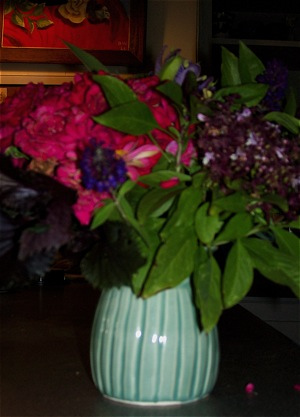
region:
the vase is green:
[86, 248, 224, 415]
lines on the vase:
[75, 257, 229, 416]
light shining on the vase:
[81, 272, 225, 412]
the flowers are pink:
[0, 61, 195, 225]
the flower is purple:
[72, 136, 132, 201]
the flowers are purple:
[191, 87, 299, 219]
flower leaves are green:
[57, 33, 299, 334]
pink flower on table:
[234, 373, 298, 401]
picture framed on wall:
[1, 4, 164, 74]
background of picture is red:
[3, 3, 131, 48]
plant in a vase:
[0, 41, 299, 406]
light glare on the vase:
[147, 333, 159, 345]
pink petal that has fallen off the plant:
[243, 380, 257, 393]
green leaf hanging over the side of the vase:
[183, 254, 225, 339]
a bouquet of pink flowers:
[0, 60, 198, 225]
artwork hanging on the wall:
[0, 1, 148, 72]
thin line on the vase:
[171, 290, 183, 401]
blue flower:
[73, 143, 133, 192]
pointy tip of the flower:
[140, 291, 150, 302]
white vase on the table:
[83, 268, 226, 406]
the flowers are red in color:
[27, 78, 177, 211]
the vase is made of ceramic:
[90, 265, 223, 405]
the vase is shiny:
[93, 273, 219, 405]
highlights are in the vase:
[134, 327, 166, 344]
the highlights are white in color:
[133, 326, 167, 348]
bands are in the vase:
[92, 285, 214, 401]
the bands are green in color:
[95, 283, 218, 399]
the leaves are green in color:
[92, 153, 298, 326]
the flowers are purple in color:
[188, 84, 293, 187]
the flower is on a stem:
[111, 193, 144, 236]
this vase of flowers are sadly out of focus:
[1, 41, 297, 416]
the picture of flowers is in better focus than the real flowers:
[1, 1, 148, 66]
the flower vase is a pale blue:
[85, 262, 220, 407]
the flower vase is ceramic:
[88, 273, 222, 406]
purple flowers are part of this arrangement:
[192, 89, 299, 230]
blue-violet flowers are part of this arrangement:
[76, 133, 129, 194]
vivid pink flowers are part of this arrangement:
[1, 69, 194, 225]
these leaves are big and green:
[102, 161, 296, 330]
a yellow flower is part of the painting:
[56, 0, 88, 24]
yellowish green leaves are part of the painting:
[9, 1, 54, 33]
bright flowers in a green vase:
[6, 36, 294, 414]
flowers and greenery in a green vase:
[6, 42, 294, 409]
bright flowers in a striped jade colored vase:
[4, 26, 296, 408]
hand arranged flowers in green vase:
[3, 36, 297, 412]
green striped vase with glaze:
[84, 266, 226, 416]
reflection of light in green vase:
[131, 326, 172, 350]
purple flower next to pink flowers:
[56, 127, 137, 199]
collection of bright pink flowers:
[1, 73, 178, 228]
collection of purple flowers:
[187, 83, 297, 215]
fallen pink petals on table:
[235, 367, 298, 404]